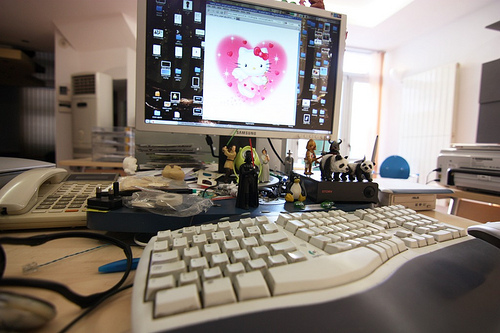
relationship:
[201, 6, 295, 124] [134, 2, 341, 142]
image on computer screen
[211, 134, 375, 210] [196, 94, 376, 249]
figurines on blue surface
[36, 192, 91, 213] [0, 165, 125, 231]
buttons on phone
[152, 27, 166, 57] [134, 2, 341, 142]
icons on computer screen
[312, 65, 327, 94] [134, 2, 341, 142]
icons on computer screen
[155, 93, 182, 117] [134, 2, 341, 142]
icons on computer screen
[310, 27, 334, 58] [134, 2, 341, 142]
icons on computer screen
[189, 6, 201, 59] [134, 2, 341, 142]
icons on computer screen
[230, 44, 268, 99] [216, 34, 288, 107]
hello kitty in heart